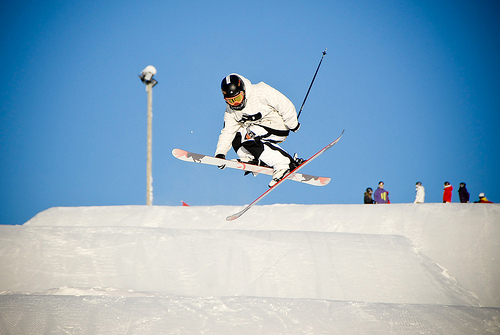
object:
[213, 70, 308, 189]
skier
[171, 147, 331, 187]
skis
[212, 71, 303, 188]
person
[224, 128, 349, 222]
skis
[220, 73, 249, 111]
helmet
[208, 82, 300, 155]
jacket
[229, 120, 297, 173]
pants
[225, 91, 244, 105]
ski googles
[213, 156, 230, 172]
glove